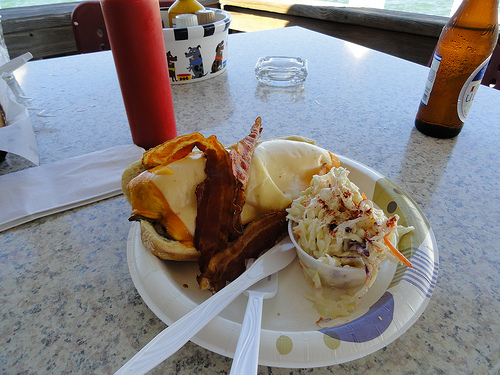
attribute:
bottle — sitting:
[416, 1, 500, 139]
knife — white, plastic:
[113, 235, 298, 374]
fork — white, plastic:
[226, 256, 279, 375]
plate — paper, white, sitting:
[124, 150, 439, 367]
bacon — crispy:
[138, 133, 237, 254]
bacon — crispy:
[228, 118, 268, 233]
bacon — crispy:
[198, 209, 288, 288]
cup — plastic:
[289, 216, 397, 285]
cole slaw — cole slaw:
[293, 169, 405, 269]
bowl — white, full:
[160, 8, 230, 86]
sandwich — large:
[122, 153, 242, 262]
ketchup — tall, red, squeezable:
[101, 0, 178, 148]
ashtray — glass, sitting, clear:
[255, 55, 308, 88]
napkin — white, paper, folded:
[1, 147, 146, 232]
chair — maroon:
[72, 0, 174, 53]